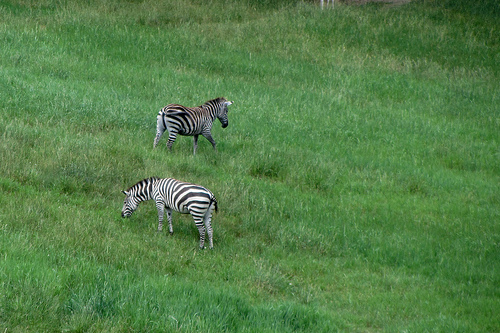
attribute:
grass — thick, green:
[65, 278, 159, 332]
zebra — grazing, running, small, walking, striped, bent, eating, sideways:
[121, 175, 217, 250]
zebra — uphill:
[153, 96, 233, 155]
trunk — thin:
[319, 1, 328, 12]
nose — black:
[222, 122, 230, 129]